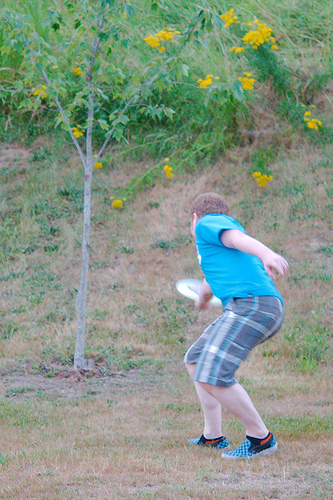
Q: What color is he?
A: White.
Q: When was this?
A: Daytime.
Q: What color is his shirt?
A: Blue.